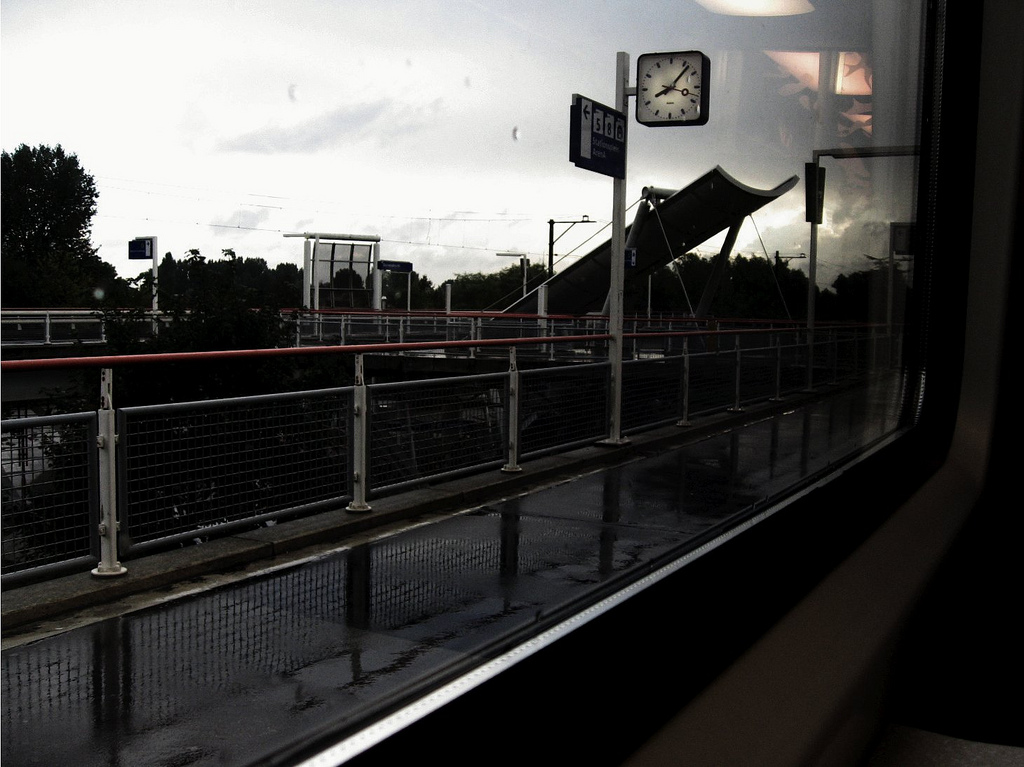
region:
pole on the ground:
[329, 455, 378, 517]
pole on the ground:
[479, 398, 530, 474]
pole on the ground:
[593, 385, 629, 443]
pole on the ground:
[503, 549, 520, 592]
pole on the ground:
[589, 489, 638, 544]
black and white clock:
[636, 55, 707, 129]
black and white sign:
[570, 85, 625, 181]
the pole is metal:
[614, 55, 628, 577]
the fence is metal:
[0, 328, 803, 584]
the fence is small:
[0, 366, 927, 763]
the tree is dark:
[0, 144, 140, 313]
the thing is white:
[289, 230, 378, 313]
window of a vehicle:
[0, 8, 928, 764]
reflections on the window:
[703, 3, 874, 136]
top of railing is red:
[0, 322, 806, 368]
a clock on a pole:
[638, 56, 716, 132]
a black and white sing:
[569, 92, 633, 182]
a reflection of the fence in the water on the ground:
[0, 399, 814, 733]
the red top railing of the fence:
[10, 326, 614, 381]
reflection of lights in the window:
[716, 0, 876, 112]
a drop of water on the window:
[506, 116, 527, 149]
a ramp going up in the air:
[449, 164, 808, 336]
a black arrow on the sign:
[577, 97, 594, 129]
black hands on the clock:
[641, 62, 692, 104]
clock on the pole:
[632, 51, 708, 128]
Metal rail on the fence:
[119, 386, 354, 536]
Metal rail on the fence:
[108, 562, 365, 725]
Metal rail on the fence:
[364, 500, 513, 621]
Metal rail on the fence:
[514, 348, 614, 456]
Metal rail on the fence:
[721, 413, 778, 487]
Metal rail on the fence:
[623, 348, 685, 437]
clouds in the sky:
[262, 79, 422, 168]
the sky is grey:
[69, 54, 145, 137]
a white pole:
[84, 380, 136, 580]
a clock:
[638, 50, 711, 123]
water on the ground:
[364, 620, 434, 671]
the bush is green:
[6, 152, 87, 248]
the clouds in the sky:
[262, 89, 390, 159]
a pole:
[600, 269, 636, 440]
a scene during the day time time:
[85, 132, 975, 747]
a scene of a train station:
[62, 34, 865, 569]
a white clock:
[628, 31, 717, 148]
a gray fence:
[18, 386, 922, 707]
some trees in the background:
[5, 111, 1018, 406]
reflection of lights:
[676, 2, 924, 170]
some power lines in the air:
[82, 152, 643, 285]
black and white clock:
[614, 43, 719, 162]